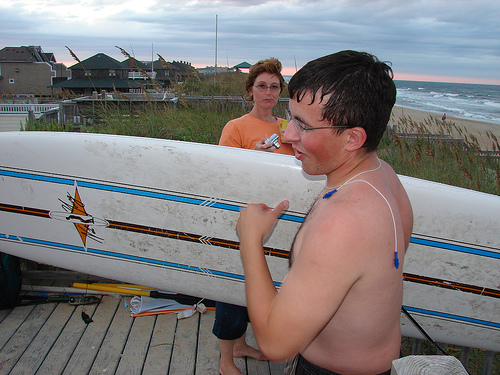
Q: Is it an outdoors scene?
A: Yes, it is outdoors.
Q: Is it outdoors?
A: Yes, it is outdoors.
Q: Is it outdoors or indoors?
A: It is outdoors.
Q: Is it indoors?
A: No, it is outdoors.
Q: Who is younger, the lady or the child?
A: The child is younger than the lady.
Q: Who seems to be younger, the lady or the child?
A: The child is younger than the lady.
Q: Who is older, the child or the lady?
A: The lady is older than the child.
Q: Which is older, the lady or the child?
A: The lady is older than the child.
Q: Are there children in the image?
A: Yes, there is a child.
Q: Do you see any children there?
A: Yes, there is a child.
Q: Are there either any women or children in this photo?
A: Yes, there is a child.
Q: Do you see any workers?
A: No, there are no workers.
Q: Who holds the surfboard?
A: The child holds the surfboard.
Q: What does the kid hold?
A: The kid holds the surf board.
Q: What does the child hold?
A: The kid holds the surf board.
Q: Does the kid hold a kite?
A: No, the kid holds the surfboard.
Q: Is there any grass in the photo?
A: Yes, there is grass.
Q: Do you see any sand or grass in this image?
A: Yes, there is grass.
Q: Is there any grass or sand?
A: Yes, there is grass.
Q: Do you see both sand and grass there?
A: Yes, there are both grass and sand.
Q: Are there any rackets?
A: No, there are no rackets.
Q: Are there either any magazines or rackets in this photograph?
A: No, there are no rackets or magazines.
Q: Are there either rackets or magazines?
A: No, there are no rackets or magazines.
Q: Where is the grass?
A: The grass is on the sand.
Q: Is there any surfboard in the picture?
A: Yes, there is a surfboard.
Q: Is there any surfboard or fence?
A: Yes, there is a surfboard.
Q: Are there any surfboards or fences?
A: Yes, there is a surfboard.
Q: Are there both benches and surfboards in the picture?
A: No, there is a surfboard but no benches.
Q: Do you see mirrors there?
A: No, there are no mirrors.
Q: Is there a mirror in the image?
A: No, there are no mirrors.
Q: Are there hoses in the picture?
A: No, there are no hoses.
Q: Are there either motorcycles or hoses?
A: No, there are no hoses or motorcycles.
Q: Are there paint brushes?
A: No, there are no paint brushes.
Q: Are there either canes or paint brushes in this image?
A: No, there are no paint brushes or canes.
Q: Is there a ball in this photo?
A: No, there are no balls.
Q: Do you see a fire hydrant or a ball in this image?
A: No, there are no balls or fire hydrants.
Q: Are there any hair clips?
A: No, there are no hair clips.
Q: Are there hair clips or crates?
A: No, there are no hair clips or crates.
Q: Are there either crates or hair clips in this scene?
A: No, there are no hair clips or crates.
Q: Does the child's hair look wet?
A: Yes, the hair is wet.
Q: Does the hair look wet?
A: Yes, the hair is wet.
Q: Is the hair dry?
A: No, the hair is wet.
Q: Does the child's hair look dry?
A: No, the hair is wet.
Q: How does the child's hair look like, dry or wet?
A: The hair is wet.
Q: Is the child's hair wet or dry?
A: The hair is wet.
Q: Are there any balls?
A: No, there are no balls.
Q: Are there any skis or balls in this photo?
A: No, there are no balls or skis.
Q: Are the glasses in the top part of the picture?
A: Yes, the glasses are in the top of the image.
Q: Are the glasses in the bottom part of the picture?
A: No, the glasses are in the top of the image.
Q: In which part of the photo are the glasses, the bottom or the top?
A: The glasses are in the top of the image.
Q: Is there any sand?
A: Yes, there is sand.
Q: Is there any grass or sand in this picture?
A: Yes, there is sand.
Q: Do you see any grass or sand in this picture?
A: Yes, there is sand.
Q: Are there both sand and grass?
A: Yes, there are both sand and grass.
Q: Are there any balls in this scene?
A: No, there are no balls.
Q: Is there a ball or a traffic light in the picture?
A: No, there are no balls or traffic lights.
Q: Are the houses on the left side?
A: Yes, the houses are on the left of the image.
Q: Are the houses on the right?
A: No, the houses are on the left of the image.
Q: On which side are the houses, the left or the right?
A: The houses are on the left of the image.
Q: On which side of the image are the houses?
A: The houses are on the left of the image.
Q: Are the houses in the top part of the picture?
A: Yes, the houses are in the top of the image.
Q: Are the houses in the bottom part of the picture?
A: No, the houses are in the top of the image.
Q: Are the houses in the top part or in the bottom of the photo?
A: The houses are in the top of the image.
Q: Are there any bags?
A: No, there are no bags.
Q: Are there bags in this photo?
A: No, there are no bags.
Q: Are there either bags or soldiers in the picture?
A: No, there are no bags or soldiers.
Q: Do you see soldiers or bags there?
A: No, there are no bags or soldiers.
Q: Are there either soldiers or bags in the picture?
A: No, there are no bags or soldiers.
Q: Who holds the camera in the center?
A: The lady holds the camera.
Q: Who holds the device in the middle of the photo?
A: The lady holds the camera.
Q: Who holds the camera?
A: The lady holds the camera.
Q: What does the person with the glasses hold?
A: The lady holds the camera.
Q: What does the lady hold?
A: The lady holds the camera.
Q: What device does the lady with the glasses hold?
A: The lady holds the camera.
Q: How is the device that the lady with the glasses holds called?
A: The device is a camera.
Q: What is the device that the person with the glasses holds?
A: The device is a camera.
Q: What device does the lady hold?
A: The lady holds the camera.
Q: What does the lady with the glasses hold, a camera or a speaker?
A: The lady holds a camera.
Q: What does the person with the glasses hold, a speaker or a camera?
A: The lady holds a camera.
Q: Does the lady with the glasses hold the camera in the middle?
A: Yes, the lady holds the camera.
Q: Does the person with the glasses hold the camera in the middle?
A: Yes, the lady holds the camera.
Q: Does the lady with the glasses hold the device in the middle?
A: Yes, the lady holds the camera.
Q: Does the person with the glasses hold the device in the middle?
A: Yes, the lady holds the camera.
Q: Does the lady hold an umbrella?
A: No, the lady holds the camera.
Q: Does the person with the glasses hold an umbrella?
A: No, the lady holds the camera.